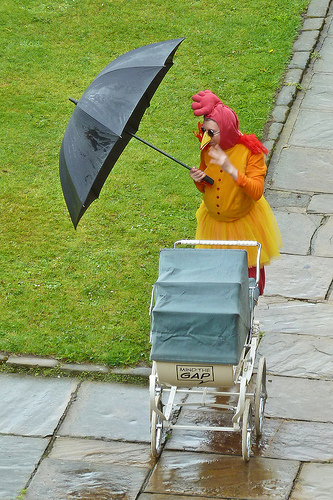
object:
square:
[52, 377, 189, 446]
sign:
[174, 364, 215, 382]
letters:
[198, 371, 209, 382]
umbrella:
[56, 38, 216, 231]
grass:
[0, 0, 314, 384]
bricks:
[56, 361, 111, 378]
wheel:
[240, 399, 255, 461]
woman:
[187, 87, 283, 299]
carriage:
[147, 234, 268, 465]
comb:
[190, 88, 223, 120]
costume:
[189, 87, 283, 298]